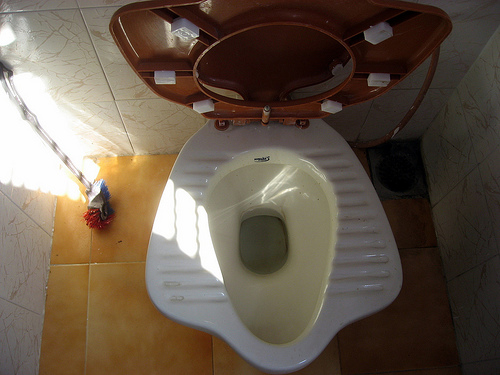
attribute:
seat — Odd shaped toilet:
[103, 8, 453, 132]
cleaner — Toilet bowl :
[373, 131, 430, 201]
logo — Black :
[249, 153, 271, 169]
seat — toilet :
[125, 126, 420, 373]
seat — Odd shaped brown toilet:
[112, 12, 424, 142]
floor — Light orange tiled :
[63, 281, 130, 331]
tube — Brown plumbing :
[388, 58, 438, 150]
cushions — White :
[136, 34, 436, 140]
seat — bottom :
[114, 10, 411, 175]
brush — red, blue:
[76, 174, 118, 234]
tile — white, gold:
[0, 150, 53, 332]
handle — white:
[1, 71, 91, 188]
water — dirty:
[216, 174, 332, 300]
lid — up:
[109, 1, 454, 127]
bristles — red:
[86, 209, 107, 228]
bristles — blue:
[95, 180, 114, 213]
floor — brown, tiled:
[45, 218, 186, 358]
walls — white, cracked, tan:
[15, 30, 223, 200]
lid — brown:
[141, 6, 428, 166]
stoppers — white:
[346, 13, 401, 75]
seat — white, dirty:
[161, 139, 418, 368]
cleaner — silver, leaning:
[10, 65, 171, 283]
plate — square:
[335, 136, 433, 215]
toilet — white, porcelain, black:
[137, 125, 437, 314]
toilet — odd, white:
[133, 139, 384, 366]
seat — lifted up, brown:
[129, 19, 354, 182]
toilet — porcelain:
[122, 33, 398, 373]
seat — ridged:
[304, 171, 390, 307]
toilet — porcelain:
[161, 126, 399, 349]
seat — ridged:
[315, 183, 407, 297]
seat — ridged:
[188, 142, 392, 326]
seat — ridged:
[304, 161, 428, 341]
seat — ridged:
[114, 134, 233, 348]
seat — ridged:
[129, 153, 268, 368]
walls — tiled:
[45, 48, 181, 150]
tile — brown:
[57, 277, 117, 339]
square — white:
[147, 67, 177, 87]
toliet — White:
[166, 130, 398, 364]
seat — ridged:
[336, 216, 382, 295]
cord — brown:
[391, 42, 441, 141]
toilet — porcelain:
[143, 0, 455, 361]